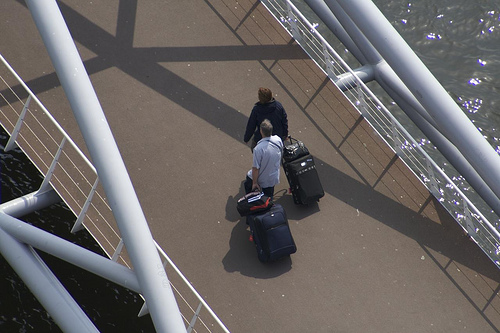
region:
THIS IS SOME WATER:
[268, 0, 498, 260]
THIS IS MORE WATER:
[0, 124, 145, 331]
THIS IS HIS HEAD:
[255, 83, 277, 103]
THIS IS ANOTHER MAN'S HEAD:
[257, 117, 277, 136]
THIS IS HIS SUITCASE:
[283, 153, 327, 210]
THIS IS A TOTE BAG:
[234, 183, 271, 218]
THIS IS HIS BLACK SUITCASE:
[241, 206, 298, 278]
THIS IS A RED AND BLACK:
[232, 189, 272, 216]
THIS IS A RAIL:
[262, 0, 496, 270]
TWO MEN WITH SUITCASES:
[227, 81, 327, 269]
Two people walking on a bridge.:
[225, 82, 330, 282]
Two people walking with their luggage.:
[222, 80, 325, 305]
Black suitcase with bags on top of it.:
[230, 182, 300, 269]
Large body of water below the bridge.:
[420, 5, 497, 64]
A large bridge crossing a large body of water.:
[15, 22, 499, 324]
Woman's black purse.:
[277, 135, 311, 161]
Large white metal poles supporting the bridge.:
[20, 0, 187, 331]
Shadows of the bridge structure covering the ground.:
[5, 2, 315, 84]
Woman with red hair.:
[251, 85, 279, 104]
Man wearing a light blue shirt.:
[242, 118, 287, 188]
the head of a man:
[248, 105, 290, 155]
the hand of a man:
[245, 176, 273, 201]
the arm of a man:
[242, 131, 281, 216]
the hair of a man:
[254, 108, 284, 161]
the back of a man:
[236, 153, 301, 209]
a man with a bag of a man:
[236, 140, 311, 245]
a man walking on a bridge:
[193, 72, 350, 282]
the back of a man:
[241, 87, 325, 185]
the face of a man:
[249, 121, 271, 143]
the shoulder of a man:
[247, 139, 276, 164]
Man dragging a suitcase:
[242, 184, 307, 267]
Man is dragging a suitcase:
[243, 182, 305, 268]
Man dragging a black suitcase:
[237, 183, 309, 267]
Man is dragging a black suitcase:
[230, 184, 307, 266]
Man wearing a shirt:
[245, 132, 287, 189]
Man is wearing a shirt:
[242, 131, 284, 186]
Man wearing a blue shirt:
[243, 132, 290, 192]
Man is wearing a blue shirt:
[245, 132, 283, 191]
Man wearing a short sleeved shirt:
[244, 137, 285, 191]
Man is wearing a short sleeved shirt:
[241, 131, 288, 190]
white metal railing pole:
[36, 138, 67, 200]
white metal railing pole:
[62, 175, 101, 241]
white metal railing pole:
[108, 238, 130, 263]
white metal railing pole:
[2, 98, 36, 158]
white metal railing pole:
[284, 3, 299, 37]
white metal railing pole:
[320, 41, 338, 81]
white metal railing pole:
[352, 78, 369, 120]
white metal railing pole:
[393, 119, 403, 154]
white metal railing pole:
[423, 156, 438, 196]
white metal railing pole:
[459, 200, 478, 239]